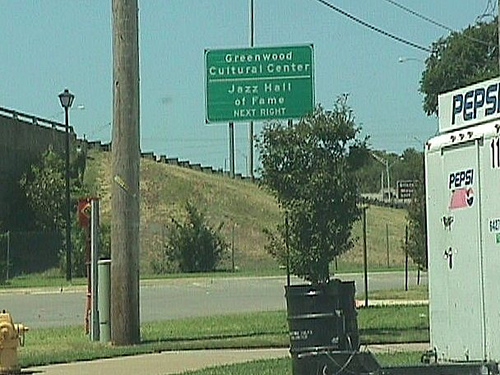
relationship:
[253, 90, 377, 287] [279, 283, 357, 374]
tree on metal drum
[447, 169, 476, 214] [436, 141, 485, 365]
sign on door